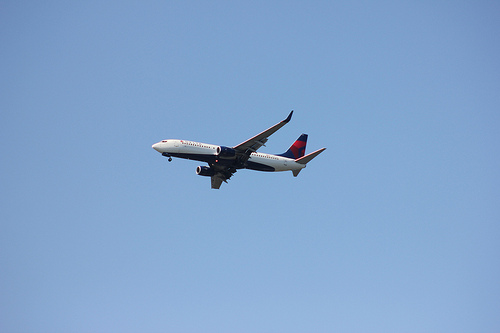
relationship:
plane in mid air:
[148, 109, 328, 191] [74, 61, 391, 261]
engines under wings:
[191, 143, 241, 182] [193, 106, 297, 193]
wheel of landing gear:
[166, 153, 175, 166] [164, 150, 179, 165]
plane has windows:
[148, 109, 328, 191] [179, 138, 216, 151]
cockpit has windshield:
[147, 134, 177, 156] [159, 138, 170, 145]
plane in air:
[148, 109, 328, 191] [5, 2, 499, 330]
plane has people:
[148, 109, 328, 191] [155, 139, 213, 150]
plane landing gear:
[148, 109, 328, 191] [164, 150, 179, 165]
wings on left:
[193, 106, 297, 193] [4, 1, 32, 329]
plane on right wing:
[148, 109, 328, 191] [231, 107, 297, 152]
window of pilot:
[156, 137, 169, 146] [159, 138, 170, 145]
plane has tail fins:
[148, 109, 328, 191] [288, 130, 334, 179]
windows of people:
[179, 138, 216, 151] [200, 141, 213, 149]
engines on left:
[191, 143, 241, 182] [4, 1, 32, 329]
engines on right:
[191, 143, 241, 182] [465, 4, 498, 332]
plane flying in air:
[148, 109, 328, 191] [5, 2, 499, 330]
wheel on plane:
[166, 153, 175, 166] [148, 109, 328, 191]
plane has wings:
[148, 109, 328, 191] [193, 106, 297, 193]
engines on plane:
[191, 143, 241, 182] [148, 109, 328, 191]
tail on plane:
[285, 131, 315, 160] [148, 109, 328, 191]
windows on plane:
[179, 138, 216, 151] [148, 109, 328, 191]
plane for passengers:
[148, 109, 328, 191] [179, 138, 216, 151]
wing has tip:
[231, 107, 297, 152] [278, 104, 298, 130]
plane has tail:
[148, 109, 328, 191] [285, 131, 315, 160]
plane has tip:
[148, 109, 328, 191] [278, 104, 298, 130]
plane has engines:
[148, 109, 328, 191] [191, 143, 241, 182]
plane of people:
[148, 109, 328, 191] [200, 141, 213, 149]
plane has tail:
[129, 79, 341, 199] [285, 131, 315, 160]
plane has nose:
[148, 109, 328, 191] [139, 137, 167, 157]